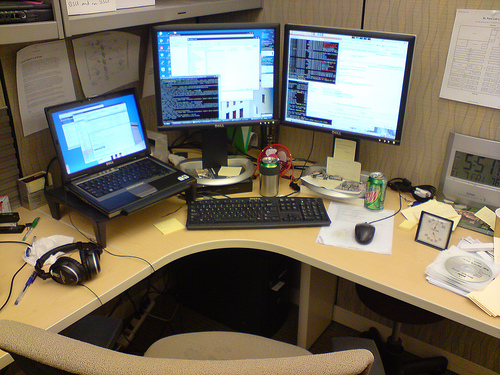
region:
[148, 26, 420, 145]
duel screen black monitors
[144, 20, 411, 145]
duel screen desk office monitors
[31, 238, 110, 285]
set of black headphones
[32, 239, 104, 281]
over the head headphones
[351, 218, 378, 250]
black computer mouse for movements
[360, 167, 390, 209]
can of soda pop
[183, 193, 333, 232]
black rectangular computer keyboard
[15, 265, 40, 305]
blue ink writing pen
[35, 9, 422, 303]
three screens on a desk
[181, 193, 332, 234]
a keyboard on a desk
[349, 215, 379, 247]
the mouse of a computer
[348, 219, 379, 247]
mouse is color black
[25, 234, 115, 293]
headphone on a desk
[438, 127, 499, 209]
the clock is color gray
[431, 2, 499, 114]
a paper on a wall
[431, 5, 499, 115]
the paper is white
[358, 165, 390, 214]
a can over a desk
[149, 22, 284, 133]
the screen is on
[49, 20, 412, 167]
three computer screens are on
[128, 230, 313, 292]
curve at edge of desk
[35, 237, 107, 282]
headphones laying on desk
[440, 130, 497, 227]
clock against the wall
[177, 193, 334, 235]
black keyboard on desk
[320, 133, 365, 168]
yellow sticky note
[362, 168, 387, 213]
green can of soda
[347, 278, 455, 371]
round stool under the desk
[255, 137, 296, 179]
small red fan on desk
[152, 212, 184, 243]
yellow sticky note on desk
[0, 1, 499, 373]
3 Computers sitting on desk.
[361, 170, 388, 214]
Soda can with silver top.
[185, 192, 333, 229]
Computer keyboard with letters and numbers.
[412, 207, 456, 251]
Black clock with numbers.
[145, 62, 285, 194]
Sticky notes on base of computer.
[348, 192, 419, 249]
Mouse with black cord.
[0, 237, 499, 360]
Headphones sitting on desk.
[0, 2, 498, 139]
Papers hanging on wall.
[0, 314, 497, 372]
Tan colored office chair.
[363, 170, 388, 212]
a can of mountain dew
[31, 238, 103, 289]
a pair of black headphones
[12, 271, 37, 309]
a blue pen on a desk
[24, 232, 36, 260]
a blue pen on a desk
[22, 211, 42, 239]
a green pen on a desk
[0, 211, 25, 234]
a stapler on a desk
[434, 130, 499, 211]
a digital clock on a desk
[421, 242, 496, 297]
a stack of discs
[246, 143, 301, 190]
a small red fan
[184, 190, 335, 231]
a black computer keyboard